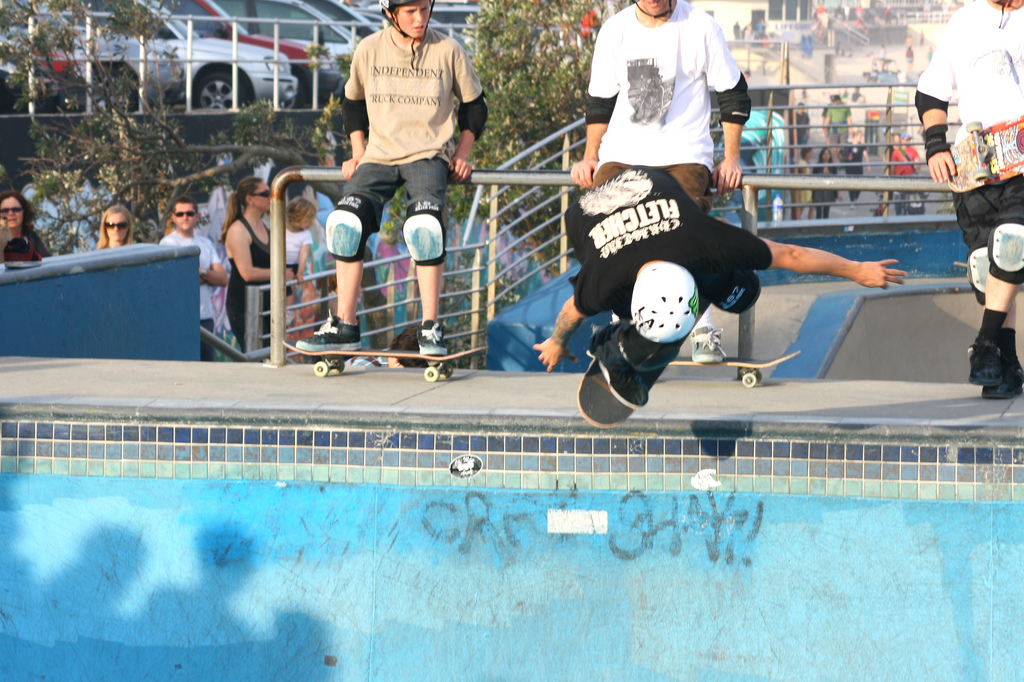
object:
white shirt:
[570, 0, 754, 175]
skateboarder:
[518, 156, 919, 422]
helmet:
[615, 248, 709, 352]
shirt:
[323, 23, 494, 177]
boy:
[283, 0, 514, 378]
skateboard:
[250, 325, 507, 389]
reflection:
[0, 487, 344, 680]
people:
[2, 487, 370, 681]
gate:
[217, 121, 594, 384]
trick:
[507, 146, 939, 451]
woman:
[210, 159, 291, 357]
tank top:
[214, 211, 287, 304]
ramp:
[0, 424, 1021, 682]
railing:
[237, 148, 1019, 391]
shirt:
[548, 162, 775, 319]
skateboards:
[268, 332, 493, 391]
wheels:
[416, 360, 444, 388]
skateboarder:
[543, 0, 764, 375]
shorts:
[589, 159, 728, 211]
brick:
[784, 470, 813, 497]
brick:
[968, 436, 1001, 472]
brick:
[117, 415, 148, 446]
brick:
[254, 455, 285, 485]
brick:
[397, 423, 420, 454]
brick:
[568, 449, 600, 480]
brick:
[748, 468, 781, 498]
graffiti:
[410, 476, 779, 595]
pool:
[0, 419, 1024, 681]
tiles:
[5, 416, 1018, 682]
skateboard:
[547, 233, 764, 434]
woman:
[74, 179, 153, 268]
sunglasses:
[97, 214, 139, 236]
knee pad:
[394, 206, 455, 274]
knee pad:
[307, 203, 374, 266]